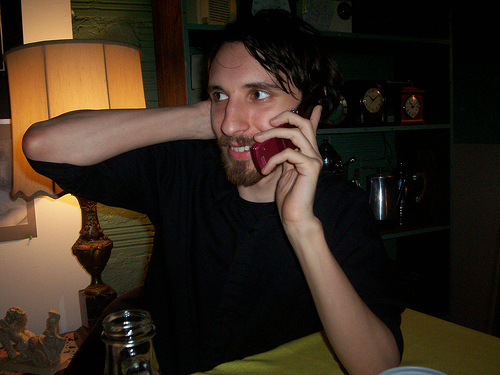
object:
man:
[19, 6, 404, 375]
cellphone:
[249, 79, 329, 171]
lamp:
[7, 38, 146, 334]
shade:
[5, 42, 147, 199]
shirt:
[28, 134, 406, 375]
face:
[209, 41, 297, 190]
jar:
[370, 173, 393, 219]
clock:
[357, 78, 389, 127]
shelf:
[153, 1, 459, 323]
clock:
[395, 82, 427, 125]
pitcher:
[387, 160, 416, 228]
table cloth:
[190, 298, 498, 375]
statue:
[0, 305, 74, 374]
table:
[0, 326, 94, 374]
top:
[103, 308, 153, 339]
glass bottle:
[96, 310, 165, 375]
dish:
[372, 364, 449, 375]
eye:
[251, 89, 273, 100]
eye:
[212, 92, 231, 103]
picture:
[0, 0, 40, 247]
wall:
[0, 0, 163, 341]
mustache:
[215, 132, 255, 144]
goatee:
[218, 157, 258, 185]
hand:
[249, 104, 325, 221]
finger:
[267, 109, 320, 151]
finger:
[251, 125, 313, 162]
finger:
[261, 147, 311, 176]